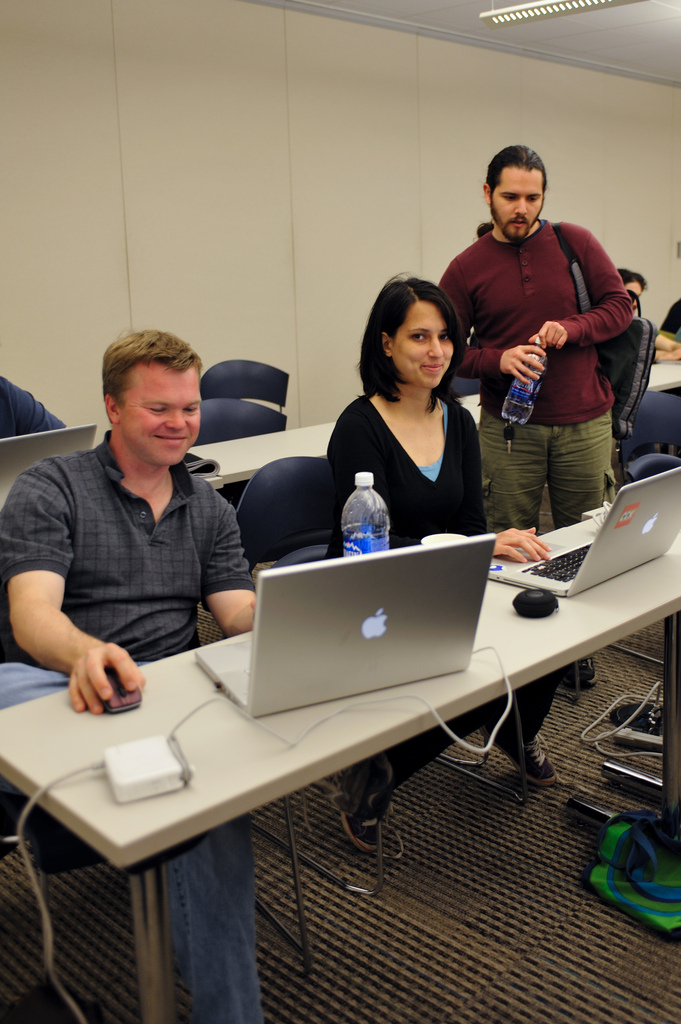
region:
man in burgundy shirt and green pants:
[465, 142, 654, 473]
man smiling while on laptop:
[19, 364, 505, 708]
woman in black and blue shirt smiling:
[351, 269, 516, 553]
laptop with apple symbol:
[202, 535, 560, 731]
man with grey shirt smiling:
[3, 335, 271, 652]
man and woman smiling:
[61, 276, 590, 638]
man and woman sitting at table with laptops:
[8, 273, 675, 857]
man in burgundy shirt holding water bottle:
[449, 146, 661, 535]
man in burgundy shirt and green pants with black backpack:
[456, 136, 678, 486]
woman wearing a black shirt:
[345, 379, 493, 535]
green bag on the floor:
[579, 802, 678, 937]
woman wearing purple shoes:
[490, 723, 560, 777]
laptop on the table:
[187, 525, 501, 722]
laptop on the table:
[489, 445, 679, 594]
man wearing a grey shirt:
[14, 437, 256, 654]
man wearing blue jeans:
[167, 831, 274, 1022]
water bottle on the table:
[325, 467, 399, 563]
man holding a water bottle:
[493, 325, 559, 434]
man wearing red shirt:
[428, 216, 636, 425]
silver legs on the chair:
[277, 824, 430, 929]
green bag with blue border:
[588, 796, 678, 903]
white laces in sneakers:
[332, 795, 449, 864]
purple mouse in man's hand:
[58, 631, 153, 738]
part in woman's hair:
[367, 254, 446, 311]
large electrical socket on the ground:
[594, 690, 659, 748]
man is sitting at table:
[0, 329, 264, 1020]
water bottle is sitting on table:
[338, 469, 388, 555]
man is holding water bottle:
[436, 144, 633, 682]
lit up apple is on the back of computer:
[358, 602, 391, 636]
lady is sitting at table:
[321, 274, 551, 846]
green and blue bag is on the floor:
[574, 807, 677, 934]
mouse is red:
[90, 658, 140, 710]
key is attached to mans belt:
[498, 418, 514, 452]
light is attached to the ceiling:
[474, 0, 679, 35]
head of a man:
[434, 107, 597, 257]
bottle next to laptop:
[253, 412, 447, 630]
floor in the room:
[383, 878, 544, 1020]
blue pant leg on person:
[131, 801, 289, 1016]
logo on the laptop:
[324, 563, 439, 672]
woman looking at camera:
[340, 260, 486, 455]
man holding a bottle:
[410, 123, 629, 443]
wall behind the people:
[37, 100, 359, 240]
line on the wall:
[229, 60, 350, 218]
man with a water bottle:
[437, 131, 635, 517]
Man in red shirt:
[431, 126, 639, 490]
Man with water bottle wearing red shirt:
[434, 127, 648, 516]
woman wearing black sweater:
[323, 267, 502, 554]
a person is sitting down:
[7, 337, 281, 1020]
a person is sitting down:
[305, 275, 561, 847]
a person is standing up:
[450, 139, 613, 693]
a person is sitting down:
[612, 264, 678, 359]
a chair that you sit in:
[183, 358, 287, 429]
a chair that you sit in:
[237, 457, 499, 831]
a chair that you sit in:
[9, 784, 324, 1001]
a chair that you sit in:
[620, 373, 679, 459]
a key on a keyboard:
[548, 569, 562, 577]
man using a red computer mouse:
[2, 325, 263, 1022]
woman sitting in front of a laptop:
[322, 268, 679, 857]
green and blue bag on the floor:
[573, 802, 680, 939]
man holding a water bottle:
[437, 140, 636, 685]